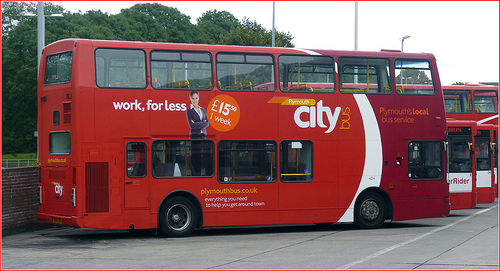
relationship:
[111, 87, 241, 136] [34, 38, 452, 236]
advertisement on bus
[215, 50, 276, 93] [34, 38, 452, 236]
window on bus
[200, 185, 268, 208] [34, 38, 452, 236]
lettering on bus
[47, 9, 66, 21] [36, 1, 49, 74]
light on pole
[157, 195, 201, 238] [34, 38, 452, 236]
tire on bus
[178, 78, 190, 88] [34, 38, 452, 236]
seat on bus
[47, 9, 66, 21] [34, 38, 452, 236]
light behind bus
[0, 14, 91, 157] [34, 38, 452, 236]
tree behind bus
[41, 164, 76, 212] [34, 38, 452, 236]
engine of bus